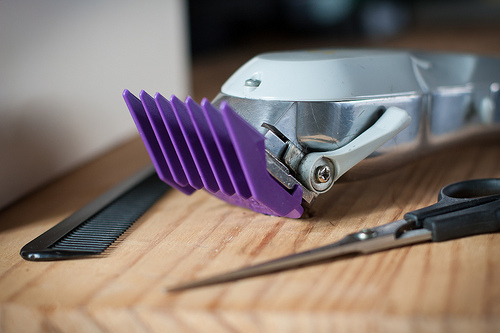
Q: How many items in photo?
A: 3.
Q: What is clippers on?
A: Desk.